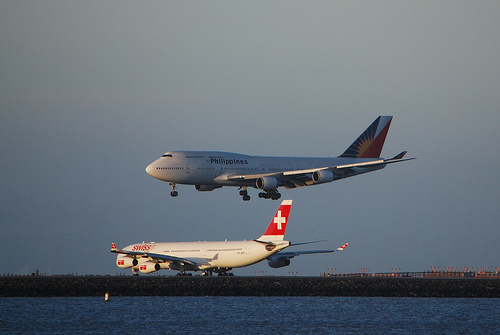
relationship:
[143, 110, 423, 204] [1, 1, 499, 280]
airplane in air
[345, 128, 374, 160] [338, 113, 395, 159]
sun on tail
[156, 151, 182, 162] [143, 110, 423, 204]
cockpit of airplane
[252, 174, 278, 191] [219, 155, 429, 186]
engine on wing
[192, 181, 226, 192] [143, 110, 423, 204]
engine on airplane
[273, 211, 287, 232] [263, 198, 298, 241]
cross on tail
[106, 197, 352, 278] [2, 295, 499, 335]
plane above ocean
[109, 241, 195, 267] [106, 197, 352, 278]
left wing of plane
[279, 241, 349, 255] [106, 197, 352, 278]
right wing of plane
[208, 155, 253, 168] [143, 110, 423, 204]
philippines on airplane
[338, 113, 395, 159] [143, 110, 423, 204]
tail of airplane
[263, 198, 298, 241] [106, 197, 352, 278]
tail of plane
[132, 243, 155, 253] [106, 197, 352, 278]
swiss on plane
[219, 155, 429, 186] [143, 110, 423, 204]
left wing on airplane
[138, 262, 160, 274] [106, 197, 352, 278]
engine on plane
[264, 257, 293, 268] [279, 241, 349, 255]
engine on right wing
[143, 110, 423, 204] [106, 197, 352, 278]
airplane above plane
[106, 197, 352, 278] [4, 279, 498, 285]
plane on runway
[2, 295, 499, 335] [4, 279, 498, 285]
ocean by runway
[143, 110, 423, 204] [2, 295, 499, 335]
airplane over ocean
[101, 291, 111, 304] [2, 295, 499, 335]
buoy in ocean